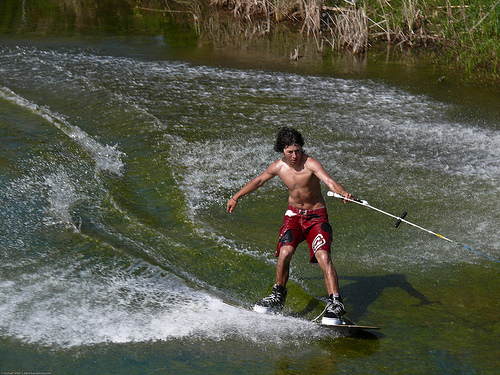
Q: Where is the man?
A: Water board.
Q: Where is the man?
A: Water.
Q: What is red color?
A: Shorts.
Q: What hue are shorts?
A: Red.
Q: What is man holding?
A: Pole.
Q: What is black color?
A: Shoes.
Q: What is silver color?
A: Pole.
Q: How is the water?
A: Murky.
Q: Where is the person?
A: On water.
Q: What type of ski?
A: Water.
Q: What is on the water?
A: Foam.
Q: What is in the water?
A: Waves.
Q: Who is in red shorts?
A: A boy.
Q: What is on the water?
A: Grass.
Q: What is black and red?
A: Shorts.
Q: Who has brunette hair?
A: A man.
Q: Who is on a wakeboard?
A: A boy.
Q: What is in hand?
A: A waterski rope.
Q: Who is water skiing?
A: Young man.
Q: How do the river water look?
A: Green and white.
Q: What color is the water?
A: Green.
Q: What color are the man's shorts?
A: Red.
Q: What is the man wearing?
A: Shorts.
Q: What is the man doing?
A: Wakeboarding.